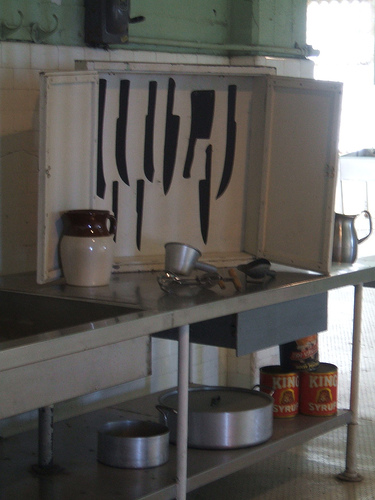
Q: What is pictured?
A: A shelf in a kitchen.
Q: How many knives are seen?
A: 9.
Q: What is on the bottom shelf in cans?
A: Syrup.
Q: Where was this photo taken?
A: In a kitchen.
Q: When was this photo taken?
A: During the day.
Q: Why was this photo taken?
A: To show what is in the kitchen.